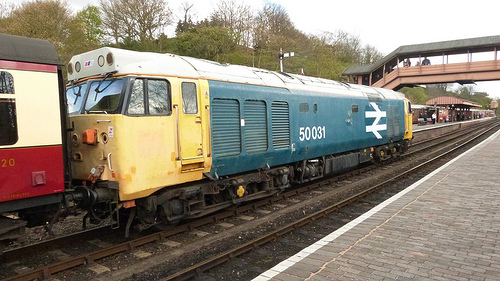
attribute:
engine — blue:
[337, 78, 423, 152]